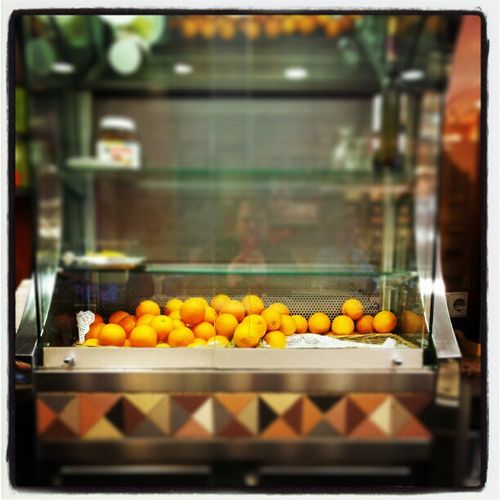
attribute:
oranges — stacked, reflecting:
[78, 286, 401, 346]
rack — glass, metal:
[29, 285, 431, 370]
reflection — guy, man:
[182, 186, 299, 300]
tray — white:
[45, 312, 424, 366]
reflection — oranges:
[84, 12, 372, 85]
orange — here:
[180, 292, 209, 328]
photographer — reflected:
[195, 190, 291, 298]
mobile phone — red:
[240, 238, 263, 274]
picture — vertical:
[21, 13, 496, 468]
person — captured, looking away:
[303, 207, 378, 285]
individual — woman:
[310, 201, 385, 297]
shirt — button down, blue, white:
[311, 247, 373, 292]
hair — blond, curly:
[321, 201, 357, 243]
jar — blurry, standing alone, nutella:
[96, 112, 148, 167]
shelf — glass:
[65, 165, 416, 193]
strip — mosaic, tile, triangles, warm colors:
[38, 386, 432, 439]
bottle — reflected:
[344, 133, 390, 204]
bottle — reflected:
[327, 117, 362, 192]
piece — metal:
[42, 341, 426, 370]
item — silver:
[38, 347, 419, 370]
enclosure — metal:
[58, 286, 392, 344]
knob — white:
[449, 291, 467, 318]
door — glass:
[49, 439, 431, 489]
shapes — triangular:
[29, 391, 432, 444]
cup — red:
[236, 237, 259, 286]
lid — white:
[102, 114, 140, 130]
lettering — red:
[103, 145, 135, 168]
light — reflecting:
[23, 83, 467, 355]